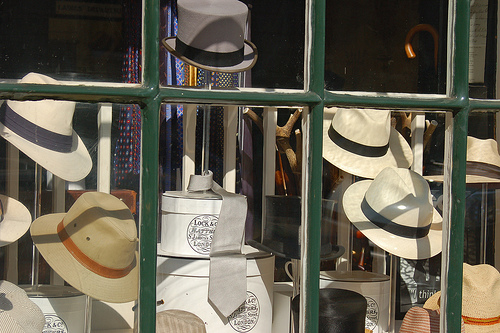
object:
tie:
[186, 169, 247, 320]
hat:
[29, 190, 141, 304]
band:
[57, 217, 134, 279]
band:
[359, 194, 432, 240]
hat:
[160, 0, 260, 74]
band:
[174, 34, 245, 68]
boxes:
[156, 189, 248, 261]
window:
[150, 93, 317, 331]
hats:
[322, 107, 418, 181]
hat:
[244, 194, 346, 263]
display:
[0, 0, 497, 332]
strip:
[0, 98, 81, 155]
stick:
[403, 23, 441, 93]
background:
[0, 0, 500, 101]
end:
[207, 297, 249, 319]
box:
[155, 242, 278, 333]